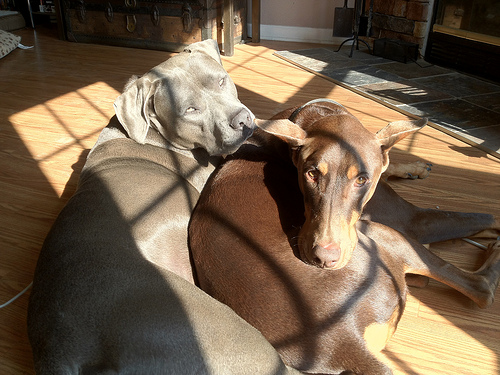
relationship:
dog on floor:
[27, 37, 302, 372] [6, 26, 498, 373]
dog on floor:
[192, 96, 499, 373] [6, 26, 498, 373]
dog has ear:
[192, 96, 499, 373] [376, 118, 430, 145]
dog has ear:
[192, 96, 499, 373] [255, 120, 312, 152]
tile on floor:
[289, 46, 351, 70] [6, 26, 498, 373]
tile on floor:
[324, 68, 401, 86] [6, 26, 498, 373]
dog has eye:
[27, 37, 302, 372] [183, 103, 196, 112]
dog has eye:
[27, 37, 302, 372] [216, 73, 227, 90]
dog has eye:
[192, 96, 499, 373] [305, 167, 323, 187]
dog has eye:
[192, 96, 499, 373] [350, 173, 372, 191]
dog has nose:
[192, 96, 499, 373] [314, 247, 340, 266]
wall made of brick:
[359, 3, 425, 51] [414, 20, 428, 35]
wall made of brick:
[359, 3, 425, 51] [374, 11, 413, 34]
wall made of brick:
[359, 3, 425, 51] [406, 2, 428, 21]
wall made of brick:
[359, 3, 425, 51] [391, 2, 406, 16]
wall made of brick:
[359, 3, 425, 51] [370, 0, 395, 15]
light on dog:
[77, 74, 255, 337] [192, 96, 499, 373]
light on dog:
[77, 74, 255, 337] [27, 37, 302, 372]